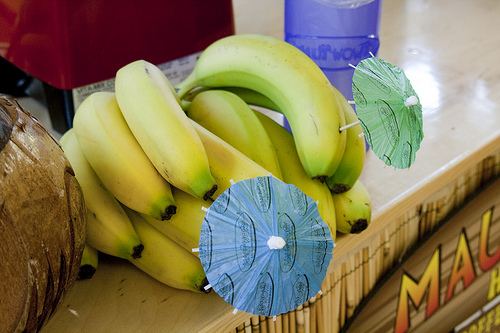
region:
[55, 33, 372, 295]
Bunch of almost ripe bananas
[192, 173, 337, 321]
Small blue paper umbrella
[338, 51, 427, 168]
Small green paper umbrella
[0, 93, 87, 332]
Hard brown casing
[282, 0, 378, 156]
Blue plastic cup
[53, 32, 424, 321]
Two umbrellas stuck into a bunch of bananas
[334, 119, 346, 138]
Puncture into a banana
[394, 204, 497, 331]
Yellow and orange lettering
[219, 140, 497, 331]
Bamboo along the bottom edge of a table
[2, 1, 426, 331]
Tropical items on a table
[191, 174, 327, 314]
mini blue umbrella with black print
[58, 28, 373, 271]
bunch of yellow bananas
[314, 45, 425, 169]
umbrella with white handle stuck in banana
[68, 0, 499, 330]
counter bananas are on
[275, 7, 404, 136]
blue bottle on countertop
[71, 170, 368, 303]
black ends of bananas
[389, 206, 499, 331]
orange and yellow lettering with black outline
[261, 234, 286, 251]
white top of umbrella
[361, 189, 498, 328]
lettered sign on front of table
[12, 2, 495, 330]
white countertop that blue bottle is on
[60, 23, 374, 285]
a bunch of bananas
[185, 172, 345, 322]
a blue coctail umbrella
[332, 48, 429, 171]
a green coctail umbrella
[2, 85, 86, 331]
the side of a wooden bowl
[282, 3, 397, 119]
a blue water bottle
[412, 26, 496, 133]
a wooden counter top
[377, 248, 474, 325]
Orange and black lettering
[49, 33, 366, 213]
the bananas are yellow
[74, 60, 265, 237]
The bananas are green at the end.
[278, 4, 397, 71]
a plastic water bottle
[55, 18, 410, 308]
the bananas are greenish yellow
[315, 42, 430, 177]
an umbrella stuck in the banana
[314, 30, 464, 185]
the umbrella is green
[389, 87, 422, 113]
the tip of the umbrella is white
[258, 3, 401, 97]
a blue cup in the background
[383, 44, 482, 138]
light on the table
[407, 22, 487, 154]
the table is tan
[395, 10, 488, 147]
the table is made of wood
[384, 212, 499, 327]
the letters are colorful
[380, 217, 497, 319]
the letters are yellow and orange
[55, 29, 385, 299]
bananas sitting on a wooden stand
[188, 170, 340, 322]
a small blue umbrella stuck in bananas on a stand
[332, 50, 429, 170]
a small green umbrella stuck in bananas on a stand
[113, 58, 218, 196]
a banana attached to a bunch of bananas on a stand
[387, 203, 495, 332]
words on a wooden stand holding bananas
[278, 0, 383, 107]
a blue cup next to a bunch of bananas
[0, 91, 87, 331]
a curved decoration next to a bunch of bananas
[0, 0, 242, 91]
a red cloth next to a bunch of bananas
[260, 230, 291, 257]
tip of a small blue umbrella near a bunch of bananas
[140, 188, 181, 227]
tip of a banana on a bunch of bananas